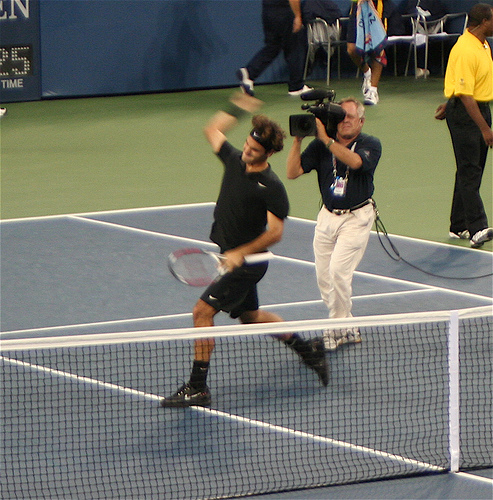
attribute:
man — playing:
[158, 92, 328, 408]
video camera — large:
[290, 89, 344, 138]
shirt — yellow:
[445, 28, 492, 99]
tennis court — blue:
[2, 200, 491, 499]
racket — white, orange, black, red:
[167, 251, 277, 285]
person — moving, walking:
[237, 0, 315, 100]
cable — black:
[374, 217, 492, 279]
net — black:
[0, 305, 490, 499]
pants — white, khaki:
[312, 198, 377, 329]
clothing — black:
[202, 141, 290, 317]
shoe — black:
[307, 336, 328, 385]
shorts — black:
[200, 251, 269, 319]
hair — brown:
[248, 114, 284, 150]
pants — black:
[445, 99, 492, 232]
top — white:
[0, 304, 492, 350]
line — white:
[69, 217, 429, 290]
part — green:
[2, 75, 491, 257]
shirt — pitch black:
[209, 142, 287, 247]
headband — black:
[250, 127, 272, 153]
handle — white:
[242, 251, 274, 265]